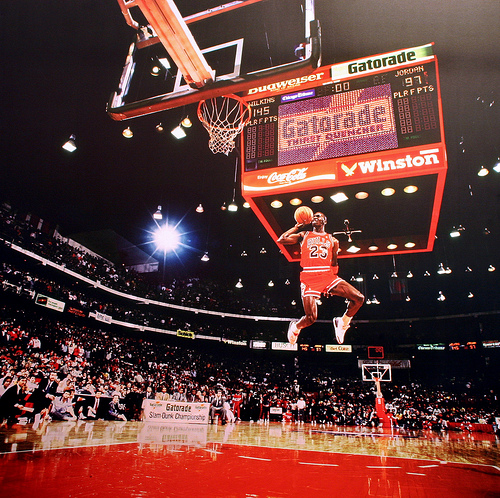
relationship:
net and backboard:
[197, 95, 252, 157] [105, 0, 324, 122]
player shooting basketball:
[276, 205, 366, 347] [293, 206, 315, 227]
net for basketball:
[197, 95, 252, 157] [293, 206, 315, 227]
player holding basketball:
[276, 205, 366, 347] [293, 206, 315, 227]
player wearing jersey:
[276, 205, 366, 347] [299, 230, 334, 272]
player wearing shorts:
[276, 205, 366, 347] [300, 266, 346, 300]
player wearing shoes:
[276, 205, 366, 347] [286, 316, 351, 347]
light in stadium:
[127, 198, 207, 277] [1, 2, 494, 496]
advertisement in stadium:
[277, 82, 399, 167] [1, 2, 494, 496]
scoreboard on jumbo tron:
[243, 64, 437, 165] [237, 41, 450, 264]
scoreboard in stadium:
[243, 64, 437, 165] [1, 2, 494, 496]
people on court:
[1, 375, 130, 428] [2, 418, 498, 497]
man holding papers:
[1, 376, 29, 431] [19, 405, 35, 414]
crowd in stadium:
[1, 201, 499, 434] [1, 2, 494, 496]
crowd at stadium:
[1, 201, 499, 434] [1, 2, 494, 496]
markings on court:
[189, 442, 500, 478] [2, 418, 498, 497]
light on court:
[127, 198, 207, 277] [2, 418, 498, 497]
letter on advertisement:
[352, 152, 379, 178] [277, 82, 399, 167]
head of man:
[307, 207, 330, 233] [1, 376, 29, 431]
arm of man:
[272, 220, 309, 248] [1, 376, 29, 431]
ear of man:
[322, 213, 329, 226] [1, 376, 29, 431]